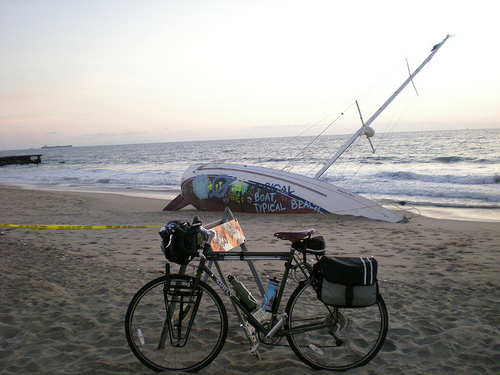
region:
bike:
[135, 212, 394, 374]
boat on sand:
[176, 141, 400, 216]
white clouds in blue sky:
[30, 7, 56, 34]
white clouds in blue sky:
[228, 3, 279, 53]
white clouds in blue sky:
[127, 43, 181, 78]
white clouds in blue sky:
[413, 112, 440, 142]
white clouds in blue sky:
[437, 105, 456, 135]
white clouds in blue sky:
[41, 80, 67, 107]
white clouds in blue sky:
[59, 28, 90, 79]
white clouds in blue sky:
[92, 70, 150, 130]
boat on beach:
[170, 145, 408, 217]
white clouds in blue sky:
[222, 35, 282, 70]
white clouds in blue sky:
[417, 86, 491, 126]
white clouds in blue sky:
[301, 42, 332, 59]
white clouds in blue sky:
[177, 66, 237, 101]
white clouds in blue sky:
[82, 29, 127, 60]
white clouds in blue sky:
[78, 71, 122, 102]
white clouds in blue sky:
[134, 6, 216, 60]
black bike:
[141, 215, 401, 373]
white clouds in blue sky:
[27, 16, 71, 40]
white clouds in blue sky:
[215, 52, 246, 80]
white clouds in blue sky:
[165, 46, 206, 63]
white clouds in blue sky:
[104, 76, 155, 93]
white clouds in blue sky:
[314, 12, 364, 70]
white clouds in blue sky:
[87, 51, 121, 75]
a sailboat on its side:
[161, 29, 462, 225]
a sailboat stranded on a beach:
[162, 30, 462, 230]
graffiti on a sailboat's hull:
[188, 169, 327, 216]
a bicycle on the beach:
[116, 205, 394, 373]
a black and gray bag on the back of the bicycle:
[310, 254, 382, 312]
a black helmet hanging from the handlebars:
[156, 214, 202, 266]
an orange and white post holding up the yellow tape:
[187, 206, 271, 352]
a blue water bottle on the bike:
[257, 276, 281, 312]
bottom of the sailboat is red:
[156, 173, 322, 222]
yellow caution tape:
[0, 214, 200, 239]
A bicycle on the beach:
[113, 205, 393, 371]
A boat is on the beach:
[155, 150, 407, 221]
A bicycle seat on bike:
[266, 220, 316, 245]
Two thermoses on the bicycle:
[220, 267, 281, 312]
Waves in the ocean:
[50, 150, 496, 200]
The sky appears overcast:
[0, 0, 496, 146]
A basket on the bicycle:
[155, 210, 211, 265]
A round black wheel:
[120, 270, 225, 370]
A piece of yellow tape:
[0, 217, 161, 232]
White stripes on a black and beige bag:
[313, 247, 379, 310]